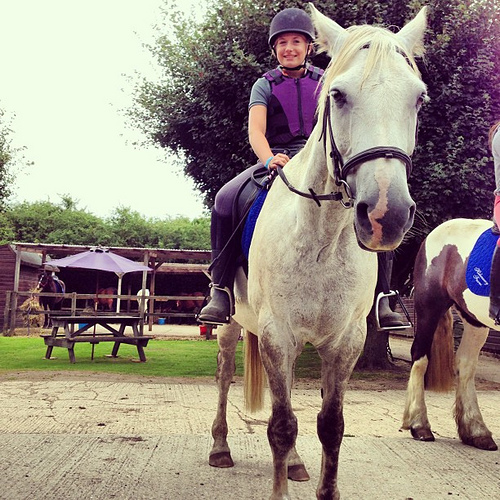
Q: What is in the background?
A: A bench.